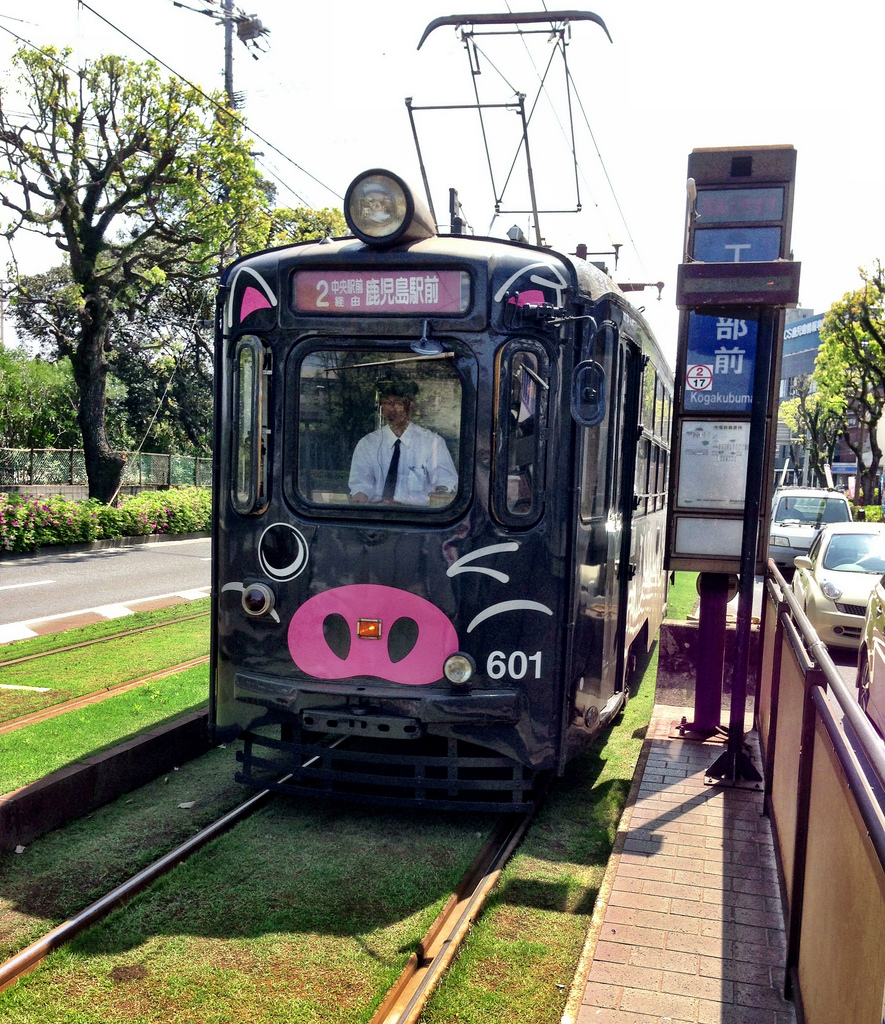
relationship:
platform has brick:
[561, 680, 801, 1024] [600, 900, 657, 928]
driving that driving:
[348, 370, 459, 507] [207, 379, 581, 829]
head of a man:
[343, 374, 425, 425] [353, 355, 451, 512]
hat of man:
[370, 371, 424, 396] [358, 368, 448, 514]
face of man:
[378, 399, 418, 411] [341, 370, 453, 519]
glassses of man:
[378, 394, 405, 416] [341, 345, 468, 515]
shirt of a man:
[353, 437, 457, 504] [337, 360, 446, 509]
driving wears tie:
[348, 370, 459, 507] [378, 431, 410, 498]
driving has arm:
[348, 370, 459, 507] [417, 431, 462, 511]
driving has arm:
[348, 370, 459, 507] [339, 431, 387, 498]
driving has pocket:
[348, 370, 459, 507] [397, 467, 435, 495]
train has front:
[195, 172, 684, 823] [201, 168, 616, 776]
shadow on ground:
[8, 724, 661, 968] [8, 724, 770, 1020]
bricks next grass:
[619, 843, 734, 968] [497, 856, 580, 968]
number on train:
[478, 641, 552, 686] [195, 172, 684, 823]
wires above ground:
[455, 13, 625, 244] [146, 724, 615, 991]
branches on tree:
[27, 132, 165, 280] [2, 32, 220, 514]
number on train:
[487, 631, 543, 695] [214, 375, 616, 902]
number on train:
[362, 274, 378, 314] [209, 213, 608, 787]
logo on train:
[281, 578, 466, 685] [195, 172, 684, 823]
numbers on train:
[487, 650, 542, 679] [195, 172, 684, 823]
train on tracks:
[195, 172, 684, 823] [2, 734, 524, 1020]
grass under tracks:
[1, 599, 660, 1022] [2, 734, 524, 1020]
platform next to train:
[552, 701, 799, 1021] [195, 172, 684, 823]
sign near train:
[663, 146, 794, 580] [195, 172, 684, 823]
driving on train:
[348, 370, 459, 507] [195, 172, 684, 823]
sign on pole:
[675, 517, 755, 556] [687, 555, 740, 743]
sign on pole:
[655, 295, 783, 578] [684, 565, 741, 735]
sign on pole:
[668, 308, 764, 417] [687, 571, 735, 738]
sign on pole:
[661, 510, 757, 580] [684, 565, 741, 735]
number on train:
[481, 642, 513, 680] [195, 172, 684, 823]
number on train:
[508, 651, 527, 679] [195, 172, 684, 823]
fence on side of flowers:
[13, 424, 202, 499] [2, 468, 212, 553]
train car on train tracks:
[182, 159, 679, 821] [16, 717, 558, 1014]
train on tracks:
[195, 172, 684, 823] [16, 717, 558, 1014]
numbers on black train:
[485, 645, 552, 682] [195, 172, 684, 823]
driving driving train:
[348, 370, 459, 507] [195, 172, 684, 823]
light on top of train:
[327, 164, 421, 254] [195, 172, 684, 823]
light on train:
[430, 648, 481, 689] [195, 172, 684, 823]